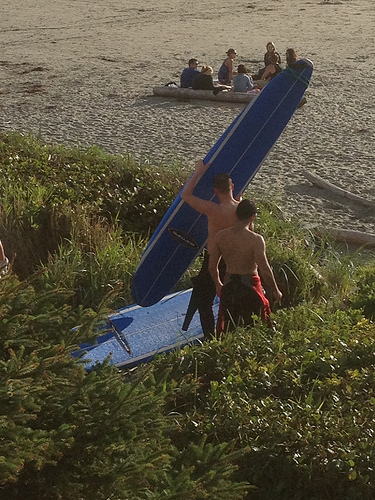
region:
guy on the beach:
[182, 49, 199, 83]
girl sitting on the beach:
[197, 62, 216, 96]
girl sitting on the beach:
[262, 40, 278, 62]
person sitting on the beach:
[232, 60, 248, 94]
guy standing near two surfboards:
[210, 204, 280, 327]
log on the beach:
[151, 78, 237, 109]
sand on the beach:
[54, 46, 108, 107]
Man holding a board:
[125, 48, 322, 347]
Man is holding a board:
[128, 55, 318, 345]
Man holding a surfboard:
[126, 55, 320, 349]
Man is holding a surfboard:
[124, 54, 320, 349]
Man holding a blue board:
[125, 51, 322, 346]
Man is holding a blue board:
[126, 56, 316, 346]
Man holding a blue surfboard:
[124, 54, 324, 342]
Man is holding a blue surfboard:
[117, 54, 319, 354]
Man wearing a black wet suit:
[174, 244, 237, 343]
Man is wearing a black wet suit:
[176, 247, 237, 358]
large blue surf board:
[129, 58, 313, 307]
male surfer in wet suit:
[206, 197, 281, 333]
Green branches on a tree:
[1, 251, 257, 499]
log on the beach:
[150, 84, 307, 107]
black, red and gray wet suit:
[215, 275, 270, 333]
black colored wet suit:
[181, 250, 227, 341]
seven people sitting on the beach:
[179, 41, 296, 90]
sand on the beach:
[1, 1, 374, 249]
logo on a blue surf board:
[167, 226, 197, 249]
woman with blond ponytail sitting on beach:
[190, 66, 225, 91]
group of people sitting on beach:
[164, 40, 316, 110]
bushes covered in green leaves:
[220, 363, 374, 493]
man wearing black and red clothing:
[206, 198, 286, 352]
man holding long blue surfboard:
[118, 58, 326, 346]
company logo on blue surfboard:
[171, 221, 201, 254]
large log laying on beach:
[301, 165, 373, 211]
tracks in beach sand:
[23, 9, 103, 56]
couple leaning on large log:
[150, 56, 223, 104]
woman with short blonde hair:
[220, 40, 237, 78]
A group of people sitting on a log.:
[156, 33, 274, 96]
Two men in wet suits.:
[134, 108, 290, 332]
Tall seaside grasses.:
[102, 385, 342, 481]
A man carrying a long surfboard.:
[145, 110, 238, 221]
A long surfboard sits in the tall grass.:
[40, 305, 179, 373]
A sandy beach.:
[48, 37, 147, 136]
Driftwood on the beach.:
[300, 166, 372, 245]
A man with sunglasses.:
[180, 54, 201, 73]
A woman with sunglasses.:
[219, 43, 239, 69]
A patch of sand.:
[162, 38, 172, 54]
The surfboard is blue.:
[210, 79, 295, 196]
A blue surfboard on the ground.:
[60, 297, 239, 351]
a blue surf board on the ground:
[68, 285, 180, 374]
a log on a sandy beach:
[152, 80, 248, 109]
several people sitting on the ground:
[188, 45, 298, 93]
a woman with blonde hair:
[201, 66, 213, 73]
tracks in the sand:
[64, 93, 190, 148]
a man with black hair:
[235, 194, 255, 218]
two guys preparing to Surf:
[162, 157, 288, 339]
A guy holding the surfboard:
[166, 154, 239, 229]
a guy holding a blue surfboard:
[174, 149, 242, 256]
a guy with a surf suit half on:
[203, 198, 284, 330]